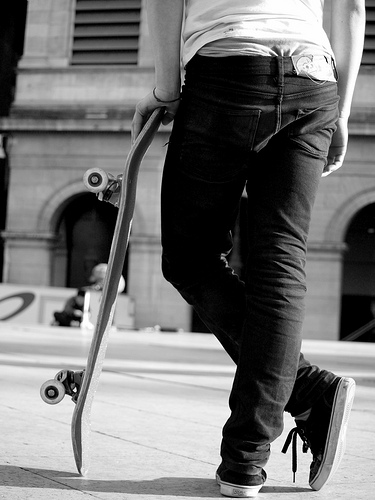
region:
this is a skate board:
[0, 104, 172, 417]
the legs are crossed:
[204, 351, 329, 496]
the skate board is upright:
[69, 120, 171, 442]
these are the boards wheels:
[36, 368, 76, 409]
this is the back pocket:
[167, 111, 266, 186]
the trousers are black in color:
[192, 173, 294, 253]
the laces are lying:
[286, 427, 305, 465]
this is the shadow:
[169, 477, 206, 498]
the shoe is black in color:
[307, 408, 328, 437]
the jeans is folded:
[224, 410, 277, 471]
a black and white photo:
[8, 6, 366, 489]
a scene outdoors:
[10, 3, 363, 476]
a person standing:
[8, 1, 364, 498]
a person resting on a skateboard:
[62, 0, 362, 492]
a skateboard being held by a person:
[35, 105, 172, 496]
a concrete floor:
[4, 316, 374, 494]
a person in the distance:
[48, 249, 144, 337]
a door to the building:
[28, 171, 141, 324]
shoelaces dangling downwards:
[271, 408, 320, 486]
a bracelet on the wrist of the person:
[138, 77, 200, 124]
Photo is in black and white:
[3, 11, 374, 489]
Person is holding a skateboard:
[34, 84, 194, 489]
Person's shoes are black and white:
[208, 348, 359, 493]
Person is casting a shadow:
[0, 434, 333, 498]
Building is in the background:
[2, 0, 371, 349]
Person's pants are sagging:
[191, 20, 345, 90]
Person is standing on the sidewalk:
[35, 367, 371, 499]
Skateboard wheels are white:
[32, 161, 128, 410]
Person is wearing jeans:
[157, 42, 354, 477]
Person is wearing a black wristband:
[132, 72, 192, 114]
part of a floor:
[148, 440, 179, 466]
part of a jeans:
[234, 413, 259, 452]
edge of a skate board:
[57, 430, 92, 463]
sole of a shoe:
[227, 483, 255, 497]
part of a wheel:
[42, 367, 67, 410]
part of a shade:
[157, 475, 185, 498]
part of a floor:
[120, 416, 150, 445]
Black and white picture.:
[10, 14, 359, 475]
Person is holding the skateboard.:
[45, 95, 172, 472]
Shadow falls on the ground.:
[2, 450, 304, 499]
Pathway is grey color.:
[119, 394, 199, 451]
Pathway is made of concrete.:
[115, 381, 191, 478]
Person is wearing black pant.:
[185, 117, 329, 340]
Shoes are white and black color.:
[214, 346, 352, 498]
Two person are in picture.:
[40, 83, 330, 434]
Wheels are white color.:
[34, 151, 112, 426]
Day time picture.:
[14, 15, 366, 482]